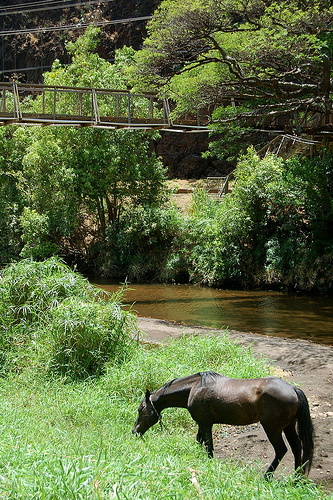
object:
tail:
[294, 387, 314, 478]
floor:
[161, 177, 238, 218]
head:
[132, 389, 162, 437]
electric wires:
[0, 0, 150, 37]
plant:
[26, 153, 64, 207]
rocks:
[236, 430, 263, 471]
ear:
[145, 389, 150, 404]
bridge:
[0, 80, 201, 133]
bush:
[5, 249, 110, 413]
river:
[129, 284, 331, 347]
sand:
[295, 347, 331, 381]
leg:
[259, 420, 288, 483]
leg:
[196, 428, 204, 447]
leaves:
[173, 68, 214, 105]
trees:
[271, 2, 333, 126]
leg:
[198, 422, 214, 459]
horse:
[131, 370, 314, 488]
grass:
[0, 381, 219, 498]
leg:
[282, 422, 301, 478]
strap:
[149, 394, 168, 431]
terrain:
[2, 177, 304, 292]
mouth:
[132, 419, 144, 437]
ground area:
[119, 312, 281, 375]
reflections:
[191, 298, 233, 322]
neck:
[150, 373, 197, 415]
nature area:
[0, 76, 333, 499]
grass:
[16, 354, 174, 498]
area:
[140, 138, 237, 218]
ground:
[0, 413, 162, 500]